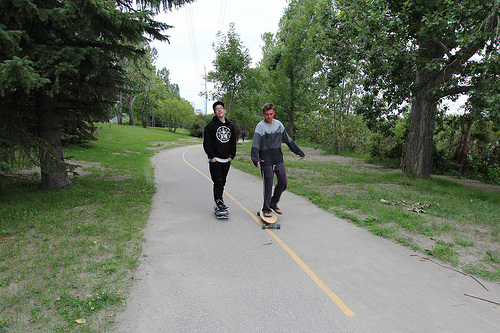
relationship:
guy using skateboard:
[247, 100, 308, 218] [254, 204, 285, 231]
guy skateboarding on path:
[178, 65, 257, 222] [113, 128, 498, 331]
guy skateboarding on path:
[247, 100, 308, 218] [113, 128, 498, 331]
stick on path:
[463, 292, 498, 304] [113, 128, 498, 331]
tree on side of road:
[3, 0, 158, 202] [142, 235, 434, 302]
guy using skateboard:
[178, 65, 257, 222] [195, 200, 247, 241]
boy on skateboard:
[258, 93, 311, 210] [255, 208, 281, 230]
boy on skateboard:
[202, 100, 237, 211] [211, 205, 230, 220]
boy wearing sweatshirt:
[202, 100, 237, 211] [204, 112, 249, 164]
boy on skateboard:
[258, 93, 311, 210] [257, 202, 308, 235]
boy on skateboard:
[202, 100, 237, 211] [257, 202, 308, 235]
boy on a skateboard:
[258, 93, 311, 210] [255, 207, 282, 229]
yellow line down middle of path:
[183, 151, 363, 332] [113, 128, 498, 331]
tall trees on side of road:
[276, 4, 498, 114] [154, 231, 429, 320]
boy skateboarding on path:
[258, 93, 311, 210] [113, 128, 498, 331]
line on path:
[183, 145, 354, 331] [113, 128, 498, 331]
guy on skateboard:
[247, 100, 308, 218] [255, 208, 281, 230]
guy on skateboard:
[178, 65, 257, 222] [212, 203, 227, 218]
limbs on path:
[408, 249, 468, 280] [113, 128, 498, 331]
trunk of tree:
[411, 80, 443, 170] [295, 5, 485, 185]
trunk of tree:
[40, 129, 77, 199] [13, 0, 175, 211]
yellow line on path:
[183, 151, 363, 332] [113, 128, 498, 331]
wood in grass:
[379, 199, 446, 215] [378, 179, 485, 233]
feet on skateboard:
[258, 202, 273, 219] [211, 202, 233, 223]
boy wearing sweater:
[258, 93, 311, 210] [250, 118, 299, 167]